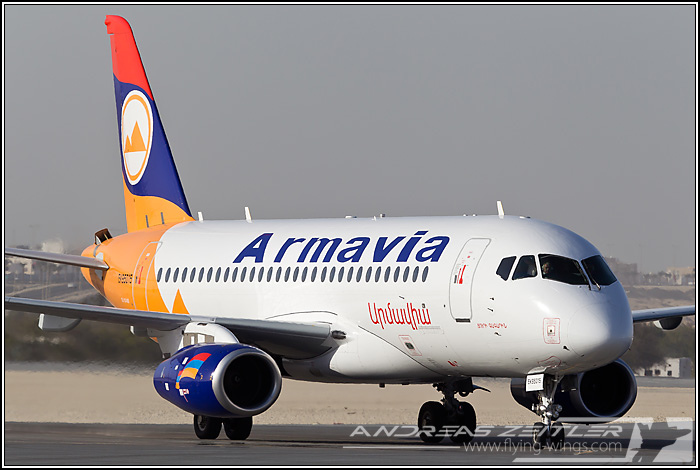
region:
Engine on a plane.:
[153, 345, 282, 426]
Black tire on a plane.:
[415, 393, 470, 449]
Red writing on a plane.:
[361, 294, 440, 334]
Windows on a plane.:
[148, 264, 432, 285]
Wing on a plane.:
[15, 285, 347, 363]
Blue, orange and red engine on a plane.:
[143, 341, 295, 424]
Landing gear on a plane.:
[408, 383, 486, 444]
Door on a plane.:
[450, 233, 495, 326]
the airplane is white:
[0, 15, 698, 449]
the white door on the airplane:
[447, 236, 490, 323]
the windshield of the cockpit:
[490, 253, 617, 291]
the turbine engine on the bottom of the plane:
[510, 359, 638, 428]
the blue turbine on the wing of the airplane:
[151, 340, 285, 420]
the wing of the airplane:
[1, 295, 331, 362]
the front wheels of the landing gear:
[529, 420, 568, 452]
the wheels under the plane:
[414, 399, 479, 447]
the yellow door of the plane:
[131, 240, 162, 310]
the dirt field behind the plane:
[1, 370, 695, 423]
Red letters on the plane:
[366, 299, 434, 335]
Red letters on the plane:
[471, 318, 509, 331]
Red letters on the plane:
[455, 249, 475, 285]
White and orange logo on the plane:
[120, 87, 153, 187]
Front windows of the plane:
[492, 250, 618, 290]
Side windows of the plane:
[154, 260, 430, 287]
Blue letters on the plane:
[233, 226, 449, 267]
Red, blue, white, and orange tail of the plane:
[60, 17, 194, 320]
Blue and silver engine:
[150, 328, 287, 420]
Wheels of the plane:
[416, 399, 476, 444]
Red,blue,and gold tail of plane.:
[102, 16, 193, 228]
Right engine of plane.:
[149, 337, 286, 427]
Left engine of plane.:
[513, 356, 646, 413]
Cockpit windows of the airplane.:
[495, 245, 626, 294]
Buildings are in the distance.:
[609, 253, 695, 293]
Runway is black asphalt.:
[4, 413, 697, 461]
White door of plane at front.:
[446, 236, 493, 325]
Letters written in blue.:
[230, 222, 451, 265]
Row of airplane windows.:
[147, 257, 434, 291]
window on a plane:
[487, 249, 538, 294]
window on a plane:
[536, 245, 595, 308]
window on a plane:
[587, 239, 629, 297]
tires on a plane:
[423, 407, 489, 440]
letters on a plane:
[373, 226, 449, 274]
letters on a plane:
[230, 219, 300, 273]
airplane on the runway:
[4, 13, 696, 452]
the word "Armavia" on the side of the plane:
[233, 230, 452, 264]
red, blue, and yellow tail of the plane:
[78, 13, 194, 326]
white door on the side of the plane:
[447, 239, 492, 319]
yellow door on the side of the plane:
[130, 240, 163, 313]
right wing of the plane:
[2, 291, 342, 361]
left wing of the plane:
[629, 303, 699, 327]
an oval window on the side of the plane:
[420, 265, 432, 283]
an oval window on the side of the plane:
[410, 265, 421, 283]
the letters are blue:
[227, 211, 463, 281]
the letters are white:
[328, 416, 628, 460]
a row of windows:
[147, 263, 429, 285]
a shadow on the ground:
[32, 411, 426, 468]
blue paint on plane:
[145, 321, 295, 429]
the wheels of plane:
[189, 394, 569, 456]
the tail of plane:
[74, 12, 187, 330]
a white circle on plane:
[110, 84, 159, 194]